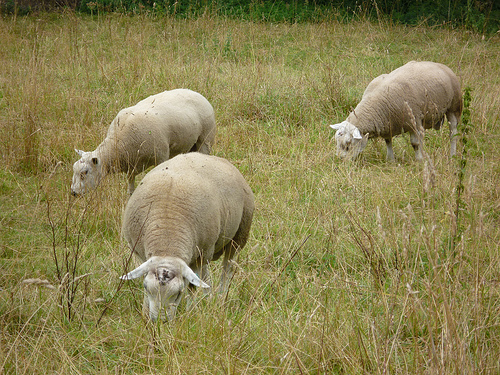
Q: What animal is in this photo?
A: Sheep.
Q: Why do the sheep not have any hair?
A: They were recently shaved.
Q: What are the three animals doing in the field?
A: Grazing on grass.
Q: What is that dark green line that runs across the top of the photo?
A: Tree line.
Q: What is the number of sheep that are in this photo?
A: Three.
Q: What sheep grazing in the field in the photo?
A: Brown sheep in front.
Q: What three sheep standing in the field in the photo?
A: Three sheep grazing.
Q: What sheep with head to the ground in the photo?
A: Sheep in back.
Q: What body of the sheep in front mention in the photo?
A: Large brown sheep.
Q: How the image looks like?
A: Good.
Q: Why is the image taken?
A: Remembrance.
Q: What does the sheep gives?
A: Wool.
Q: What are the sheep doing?
A: Grazing.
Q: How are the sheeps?
A: White.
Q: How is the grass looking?
A: Dry.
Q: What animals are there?
A: Sheep.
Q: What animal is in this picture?
A: Sheep.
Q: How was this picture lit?
A: Sunlight.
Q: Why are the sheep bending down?
A: Grazing.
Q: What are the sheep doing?
A: Eating.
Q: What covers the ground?
A: Grass.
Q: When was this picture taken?
A: Daytime.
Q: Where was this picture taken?
A: Field.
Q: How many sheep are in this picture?
A: Three.